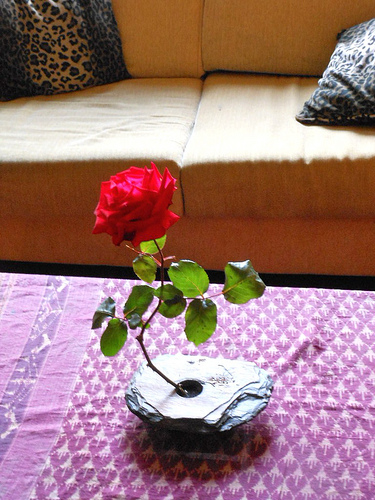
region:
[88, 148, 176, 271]
the rose is red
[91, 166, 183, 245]
A red rose flower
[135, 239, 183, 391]
A curved stem on a rose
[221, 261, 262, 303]
A curled green leaf on a rose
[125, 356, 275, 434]
A rock vase holding a rose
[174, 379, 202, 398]
A hole in a stone vase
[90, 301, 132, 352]
Leaves on a rose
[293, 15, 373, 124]
A pillow on a couch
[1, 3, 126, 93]
A leopard print patterned pillow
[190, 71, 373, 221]
A tan cushion on a couch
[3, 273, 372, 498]
A purple cloth on a table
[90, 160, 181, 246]
A red rose.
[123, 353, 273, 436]
A grey rock on a table.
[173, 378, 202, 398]
Hole in a grey rock.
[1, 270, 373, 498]
A purple and white table cover.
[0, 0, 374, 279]
Orange couch with pillows.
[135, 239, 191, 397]
A long brown stem.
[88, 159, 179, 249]
A red rose that is opened.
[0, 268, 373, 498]
Lavender and purple table cloth with white on it.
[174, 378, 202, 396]
Round dark hole in a rock.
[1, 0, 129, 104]
Cheetah print pillow.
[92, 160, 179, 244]
red rose is alive and visible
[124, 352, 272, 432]
gray rock is holding a red rose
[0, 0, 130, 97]
leapard print pillow is sitting on a couch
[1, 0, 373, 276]
cream colored couch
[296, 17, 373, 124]
leopard print pillow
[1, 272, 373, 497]
table cloth is purple and white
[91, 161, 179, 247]
rose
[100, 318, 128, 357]
leaf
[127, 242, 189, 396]
rose has a long brown stem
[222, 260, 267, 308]
green leaf on flower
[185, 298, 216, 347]
green leaf on flower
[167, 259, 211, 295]
green leaf on flower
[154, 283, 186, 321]
green leaf on flower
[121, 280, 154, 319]
green leaf on flower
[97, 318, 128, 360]
green leaf on flower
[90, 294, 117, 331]
green leaf on flower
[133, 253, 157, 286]
green leaf on flower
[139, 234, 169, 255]
green leaf on flower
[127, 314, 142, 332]
green leaf on flower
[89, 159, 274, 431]
Red rose in a rock vase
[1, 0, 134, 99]
Animal print pillow on a couch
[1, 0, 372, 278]
Tan sofa with pillows behind a rose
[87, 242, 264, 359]
Green leaves on a flower stem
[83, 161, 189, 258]
rose is red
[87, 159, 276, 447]
rose is in a rock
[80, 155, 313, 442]
rose is on a table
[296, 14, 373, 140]
pillow is leopard print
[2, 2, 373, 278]
pillows on the sofa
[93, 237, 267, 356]
leaves on the stem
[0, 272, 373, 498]
purple cover on the table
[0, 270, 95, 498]
lilac stripe on the cover